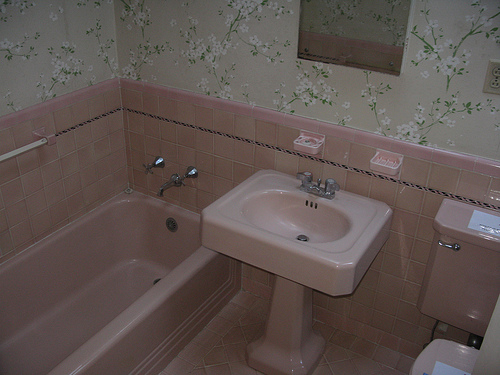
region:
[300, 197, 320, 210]
three small slots in sink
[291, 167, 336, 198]
silver faucets on top of sink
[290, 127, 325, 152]
pink toothbrush holder on wall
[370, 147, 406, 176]
pink soap dish attached to wall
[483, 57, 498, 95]
two plug outlet on the wall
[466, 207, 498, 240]
white sign on top of toilet tank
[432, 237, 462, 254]
silver toilet handle on pink toilet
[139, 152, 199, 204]
sliver faucets on wall belong to tub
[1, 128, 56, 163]
white and pink towel rack above tub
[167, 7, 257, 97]
tan wallpaper with whit flowers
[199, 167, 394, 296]
a pink bathroom sink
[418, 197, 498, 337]
a pink toilet tank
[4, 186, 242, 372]
a pink bath tub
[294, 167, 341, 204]
a chrome bathroom faucet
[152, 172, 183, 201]
a chrome bath tub faucet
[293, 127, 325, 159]
a pink soap dish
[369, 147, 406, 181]
a pink soap dish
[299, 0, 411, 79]
a wall mounted vanity mirror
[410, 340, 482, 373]
a toilet seat lid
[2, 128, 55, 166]
a pink and white towel bar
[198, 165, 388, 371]
pink handwash in a bathroom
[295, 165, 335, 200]
gray metal tap in handwash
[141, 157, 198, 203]
gray metal tab of bathtub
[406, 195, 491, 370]
pink toilet in bathroom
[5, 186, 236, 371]
pink bathtub in bathroom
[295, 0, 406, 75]
mirror on top of handwash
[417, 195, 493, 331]
pink water tank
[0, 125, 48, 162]
white largepole on top of pink bathtub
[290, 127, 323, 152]
small pink soapdish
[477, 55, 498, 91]
small white plug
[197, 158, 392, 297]
pink bathroom sink and faucet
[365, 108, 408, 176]
pink soap dish with flowers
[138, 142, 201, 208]
bathtub faucet with pink tile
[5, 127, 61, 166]
pink tile and towel rack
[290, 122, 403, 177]
two pink soap dishes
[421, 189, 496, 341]
pink toilet water tank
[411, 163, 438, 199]
black trim on pink tile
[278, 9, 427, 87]
bathroom mirror with floral pattern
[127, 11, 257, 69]
flower wallpaper inside bathroom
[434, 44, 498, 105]
bathroom electrical socket with flower wallpaper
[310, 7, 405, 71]
a mirror on the wall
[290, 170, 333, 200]
the faucet handles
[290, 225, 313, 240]
the drain in the sink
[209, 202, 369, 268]
the sink is white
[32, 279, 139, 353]
the bathroom tub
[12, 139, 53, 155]
a handle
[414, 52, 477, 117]
wallpapaer on the wall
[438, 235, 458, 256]
a hanle on the toilet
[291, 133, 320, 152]
toothbrush holder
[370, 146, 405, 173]
soap dish